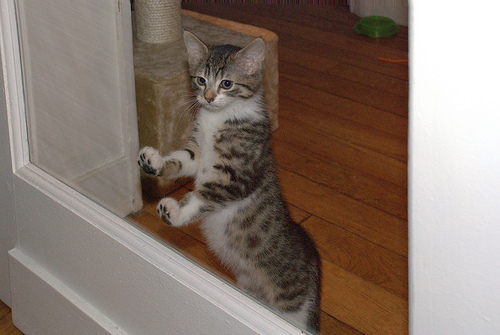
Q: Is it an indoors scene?
A: Yes, it is indoors.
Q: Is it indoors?
A: Yes, it is indoors.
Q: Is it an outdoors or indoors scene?
A: It is indoors.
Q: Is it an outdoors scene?
A: No, it is indoors.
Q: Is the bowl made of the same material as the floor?
A: No, the bowl is made of plastic and the floor is made of wood.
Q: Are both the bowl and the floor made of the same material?
A: No, the bowl is made of plastic and the floor is made of wood.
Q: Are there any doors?
A: Yes, there is a door.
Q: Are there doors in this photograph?
A: Yes, there is a door.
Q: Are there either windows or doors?
A: Yes, there is a door.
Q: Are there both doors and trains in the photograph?
A: No, there is a door but no trains.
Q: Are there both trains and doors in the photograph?
A: No, there is a door but no trains.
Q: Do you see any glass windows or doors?
A: Yes, there is a glass door.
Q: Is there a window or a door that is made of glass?
A: Yes, the door is made of glass.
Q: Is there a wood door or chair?
A: Yes, there is a wood door.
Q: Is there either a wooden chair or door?
A: Yes, there is a wood door.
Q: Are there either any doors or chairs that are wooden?
A: Yes, the door is wooden.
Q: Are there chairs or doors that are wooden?
A: Yes, the door is wooden.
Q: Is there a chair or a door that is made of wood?
A: Yes, the door is made of wood.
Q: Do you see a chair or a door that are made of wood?
A: Yes, the door is made of wood.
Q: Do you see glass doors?
A: Yes, there is a door that is made of glass.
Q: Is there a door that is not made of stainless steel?
A: Yes, there is a door that is made of glass.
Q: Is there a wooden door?
A: Yes, there is a wood door.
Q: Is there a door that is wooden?
A: Yes, there is a door that is wooden.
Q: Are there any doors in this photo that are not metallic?
A: Yes, there is a wooden door.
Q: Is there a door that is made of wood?
A: Yes, there is a door that is made of wood.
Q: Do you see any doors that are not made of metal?
A: Yes, there is a door that is made of wood.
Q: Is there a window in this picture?
A: No, there are no windows.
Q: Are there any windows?
A: No, there are no windows.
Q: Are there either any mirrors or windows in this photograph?
A: No, there are no windows or mirrors.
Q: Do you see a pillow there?
A: No, there are no pillows.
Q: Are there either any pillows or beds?
A: No, there are no pillows or beds.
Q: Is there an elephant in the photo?
A: No, there are no elephants.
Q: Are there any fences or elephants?
A: No, there are no elephants or fences.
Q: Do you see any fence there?
A: No, there are no fences.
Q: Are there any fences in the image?
A: No, there are no fences.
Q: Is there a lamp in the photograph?
A: No, there are no lamps.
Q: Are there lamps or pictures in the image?
A: No, there are no lamps or pictures.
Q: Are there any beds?
A: No, there are no beds.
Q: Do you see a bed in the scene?
A: No, there are no beds.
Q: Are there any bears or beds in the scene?
A: No, there are no beds or bears.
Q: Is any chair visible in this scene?
A: No, there are no chairs.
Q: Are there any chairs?
A: No, there are no chairs.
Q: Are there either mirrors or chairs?
A: No, there are no chairs or mirrors.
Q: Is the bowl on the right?
A: Yes, the bowl is on the right of the image.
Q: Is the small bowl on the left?
A: No, the bowl is on the right of the image.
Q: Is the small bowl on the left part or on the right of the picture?
A: The bowl is on the right of the image.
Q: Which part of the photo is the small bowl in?
A: The bowl is on the right of the image.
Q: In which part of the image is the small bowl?
A: The bowl is on the right of the image.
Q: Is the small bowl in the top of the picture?
A: Yes, the bowl is in the top of the image.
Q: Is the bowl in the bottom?
A: No, the bowl is in the top of the image.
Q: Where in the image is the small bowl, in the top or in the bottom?
A: The bowl is in the top of the image.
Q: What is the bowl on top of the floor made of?
A: The bowl is made of plastic.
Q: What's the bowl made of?
A: The bowl is made of plastic.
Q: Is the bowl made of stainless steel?
A: No, the bowl is made of plastic.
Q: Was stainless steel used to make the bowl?
A: No, the bowl is made of plastic.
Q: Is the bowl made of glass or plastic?
A: The bowl is made of plastic.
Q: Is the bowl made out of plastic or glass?
A: The bowl is made of plastic.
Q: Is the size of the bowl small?
A: Yes, the bowl is small.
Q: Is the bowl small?
A: Yes, the bowl is small.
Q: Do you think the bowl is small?
A: Yes, the bowl is small.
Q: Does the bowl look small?
A: Yes, the bowl is small.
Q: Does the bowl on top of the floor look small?
A: Yes, the bowl is small.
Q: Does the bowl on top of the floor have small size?
A: Yes, the bowl is small.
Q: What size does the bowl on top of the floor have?
A: The bowl has small size.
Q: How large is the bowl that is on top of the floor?
A: The bowl is small.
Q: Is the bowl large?
A: No, the bowl is small.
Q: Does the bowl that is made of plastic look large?
A: No, the bowl is small.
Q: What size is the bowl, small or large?
A: The bowl is small.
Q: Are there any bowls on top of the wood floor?
A: Yes, there is a bowl on top of the floor.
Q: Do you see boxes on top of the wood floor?
A: No, there is a bowl on top of the floor.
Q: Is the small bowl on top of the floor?
A: Yes, the bowl is on top of the floor.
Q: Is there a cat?
A: Yes, there is a cat.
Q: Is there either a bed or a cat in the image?
A: Yes, there is a cat.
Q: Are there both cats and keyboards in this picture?
A: No, there is a cat but no keyboards.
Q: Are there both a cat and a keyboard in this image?
A: No, there is a cat but no keyboards.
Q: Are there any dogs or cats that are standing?
A: Yes, the cat is standing.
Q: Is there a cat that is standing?
A: Yes, there is a cat that is standing.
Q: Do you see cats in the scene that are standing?
A: Yes, there is a cat that is standing.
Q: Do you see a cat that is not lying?
A: Yes, there is a cat that is standing .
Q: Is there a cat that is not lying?
A: Yes, there is a cat that is standing.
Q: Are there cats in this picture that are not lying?
A: Yes, there is a cat that is standing.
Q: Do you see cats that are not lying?
A: Yes, there is a cat that is standing .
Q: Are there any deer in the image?
A: No, there are no deer.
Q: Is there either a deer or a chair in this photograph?
A: No, there are no deer or chairs.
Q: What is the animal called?
A: The animal is a cat.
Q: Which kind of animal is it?
A: The animal is a cat.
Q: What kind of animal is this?
A: This is a cat.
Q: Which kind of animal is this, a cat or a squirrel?
A: This is a cat.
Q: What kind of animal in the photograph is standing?
A: The animal is a cat.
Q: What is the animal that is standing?
A: The animal is a cat.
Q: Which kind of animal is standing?
A: The animal is a cat.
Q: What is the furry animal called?
A: The animal is a cat.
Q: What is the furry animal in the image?
A: The animal is a cat.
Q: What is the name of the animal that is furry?
A: The animal is a cat.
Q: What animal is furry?
A: The animal is a cat.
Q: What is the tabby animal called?
A: The animal is a cat.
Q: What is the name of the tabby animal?
A: The animal is a cat.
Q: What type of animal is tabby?
A: The animal is a cat.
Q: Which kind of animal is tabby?
A: The animal is a cat.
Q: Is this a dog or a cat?
A: This is a cat.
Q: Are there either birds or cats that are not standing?
A: No, there is a cat but it is standing.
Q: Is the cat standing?
A: Yes, the cat is standing.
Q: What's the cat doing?
A: The cat is standing.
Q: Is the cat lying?
A: No, the cat is standing.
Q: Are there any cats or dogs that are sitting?
A: No, there is a cat but it is standing.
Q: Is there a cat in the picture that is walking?
A: No, there is a cat but it is standing.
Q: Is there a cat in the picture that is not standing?
A: No, there is a cat but it is standing.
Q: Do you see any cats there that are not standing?
A: No, there is a cat but it is standing.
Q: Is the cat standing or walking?
A: The cat is standing.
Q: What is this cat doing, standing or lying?
A: The cat is standing.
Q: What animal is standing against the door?
A: The cat is standing against the door.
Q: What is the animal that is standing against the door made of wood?
A: The animal is a cat.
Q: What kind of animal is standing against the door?
A: The animal is a cat.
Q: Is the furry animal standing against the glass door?
A: Yes, the cat is standing against the door.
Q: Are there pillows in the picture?
A: No, there are no pillows.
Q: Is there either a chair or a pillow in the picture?
A: No, there are no pillows or chairs.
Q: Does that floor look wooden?
A: Yes, the floor is wooden.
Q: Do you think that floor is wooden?
A: Yes, the floor is wooden.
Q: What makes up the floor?
A: The floor is made of wood.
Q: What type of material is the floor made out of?
A: The floor is made of wood.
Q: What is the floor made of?
A: The floor is made of wood.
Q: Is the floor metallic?
A: No, the floor is wooden.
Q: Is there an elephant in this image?
A: No, there are no elephants.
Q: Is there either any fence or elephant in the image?
A: No, there are no elephants or fences.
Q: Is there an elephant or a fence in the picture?
A: No, there are no elephants or fences.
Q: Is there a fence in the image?
A: No, there are no fences.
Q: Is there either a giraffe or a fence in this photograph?
A: No, there are no fences or giraffes.